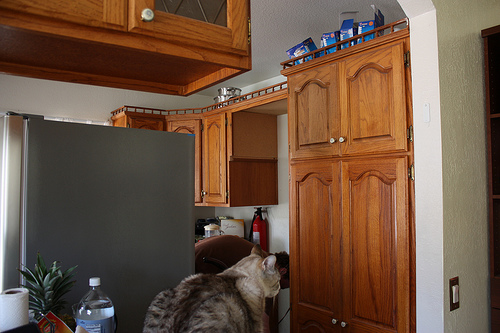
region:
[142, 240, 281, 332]
Grey cat sitting in kitchen.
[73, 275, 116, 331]
Bottle of water in kitchen.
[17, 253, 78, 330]
Pineapple sitting in kitchen.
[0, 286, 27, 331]
Roll of paper towels in kitchen.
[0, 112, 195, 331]
Grey refrigerator in kitchen.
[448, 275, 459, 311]
Light switch in kitchen.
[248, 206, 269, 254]
Red fire extinguisher in kitchen.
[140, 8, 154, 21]
White knob for a kitchen cupboard.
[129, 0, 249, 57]
Wood and glass door of kitchen cupboard.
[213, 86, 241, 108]
Grey pots stacked in kitchen.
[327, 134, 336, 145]
a white cabinet knob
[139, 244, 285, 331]
a large gray and black cat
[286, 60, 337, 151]
a brown cabinet door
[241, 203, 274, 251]
part of a red fire extinguisher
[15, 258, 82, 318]
part of a green plant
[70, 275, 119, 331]
a water bottle with a white top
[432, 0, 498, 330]
part of a white wall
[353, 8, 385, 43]
an opened blue box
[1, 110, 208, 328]
part of a large refrigerator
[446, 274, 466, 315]
a wall light switch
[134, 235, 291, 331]
a cat sits on a counter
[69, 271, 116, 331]
a bottle near a cat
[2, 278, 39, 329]
a roll of paper towels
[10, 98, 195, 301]
a refrigerator color gray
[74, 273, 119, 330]
a bottle with white cup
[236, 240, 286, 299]
head of cat is brown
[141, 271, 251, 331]
body of cat is black and brown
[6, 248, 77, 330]
a pineapple next paper towels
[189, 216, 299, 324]
a person behind a cat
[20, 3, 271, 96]
cabinet on top of refrigerator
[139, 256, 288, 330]
Backside gray black sitting cat.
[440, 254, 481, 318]
Push bar light wall receptical.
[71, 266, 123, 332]
2L bottle clear liquid counter.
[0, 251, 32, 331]
White paper towel roll.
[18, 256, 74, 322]
Potted thick leaf green plant.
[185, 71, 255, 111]
Two silver stainless steel mixing bowls.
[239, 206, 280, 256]
Red kitchen fire extinguisher.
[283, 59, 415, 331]
Tall wooden kitchen cabinet.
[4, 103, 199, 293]
Large stainless steele refrigerator.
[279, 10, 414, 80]
Catch-all top kitchen cabinet.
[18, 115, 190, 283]
grey door on fridge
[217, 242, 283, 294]
cat has grey head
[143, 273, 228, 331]
cat has dark grey fur on back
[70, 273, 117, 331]
tonic water behind cat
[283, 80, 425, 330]
brown and wooden cabinet doors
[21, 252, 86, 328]
green pineapple fronds beside water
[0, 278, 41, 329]
white paper towel roll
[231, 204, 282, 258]
red fire extinguisher behind cat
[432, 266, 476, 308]
silver and white light switch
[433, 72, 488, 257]
white wall near light switch